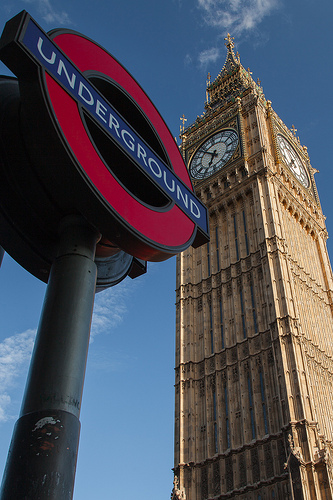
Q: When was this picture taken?
A: Daytime.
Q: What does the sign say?
A: UNDERGROUND.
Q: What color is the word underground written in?
A: White.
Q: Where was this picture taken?
A: London.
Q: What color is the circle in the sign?
A: Red.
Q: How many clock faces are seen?
A: 2.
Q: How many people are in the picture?
A: None.